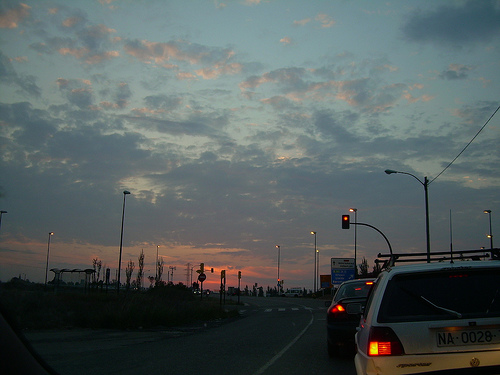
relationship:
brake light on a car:
[367, 339, 391, 357] [354, 262, 499, 373]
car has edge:
[325, 278, 379, 357] [372, 272, 389, 320]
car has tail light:
[344, 243, 495, 374] [361, 330, 393, 357]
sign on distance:
[196, 272, 206, 284] [12, 264, 342, 324]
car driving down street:
[304, 259, 392, 357] [28, 300, 339, 370]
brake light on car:
[368, 340, 391, 356] [318, 270, 381, 361]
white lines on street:
[251, 305, 324, 312] [237, 293, 322, 368]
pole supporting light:
[413, 169, 437, 264] [384, 163, 393, 180]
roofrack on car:
[373, 248, 499, 265] [354, 262, 499, 373]